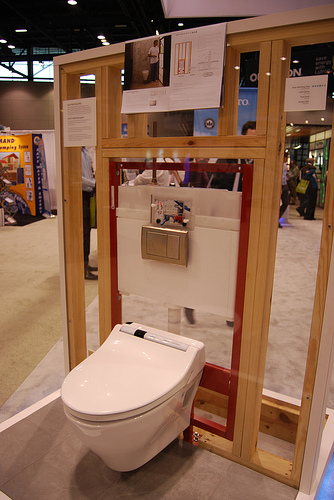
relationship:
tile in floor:
[136, 447, 299, 500] [3, 376, 295, 498]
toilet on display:
[48, 312, 215, 479] [52, 2, 333, 492]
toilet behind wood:
[48, 312, 215, 479] [53, 90, 319, 272]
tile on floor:
[19, 434, 79, 491] [1, 407, 298, 498]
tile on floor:
[204, 461, 299, 498] [3, 197, 332, 498]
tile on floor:
[0, 434, 120, 500] [3, 197, 332, 498]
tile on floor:
[136, 447, 299, 500] [3, 197, 332, 498]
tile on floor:
[195, 457, 258, 495] [154, 461, 266, 498]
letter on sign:
[0, 137, 16, 143] [0, 136, 36, 216]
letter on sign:
[0, 146, 29, 149] [0, 136, 36, 216]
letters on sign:
[0, 137, 15, 143] [0, 135, 32, 152]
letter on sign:
[310, 84, 316, 87] [280, 72, 328, 114]